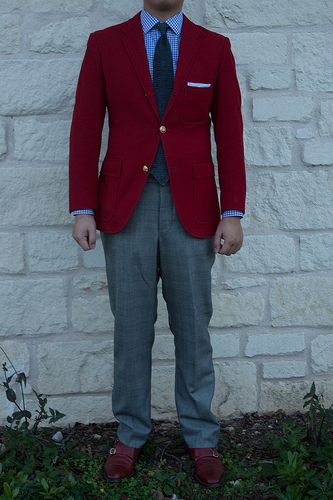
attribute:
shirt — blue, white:
[138, 8, 183, 81]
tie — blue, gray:
[152, 19, 172, 191]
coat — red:
[68, 11, 247, 242]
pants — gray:
[101, 174, 220, 450]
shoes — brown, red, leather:
[101, 441, 227, 488]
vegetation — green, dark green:
[0, 346, 328, 498]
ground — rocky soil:
[3, 408, 331, 499]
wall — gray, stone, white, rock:
[0, 3, 331, 428]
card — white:
[186, 81, 214, 88]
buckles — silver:
[105, 447, 222, 459]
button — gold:
[157, 125, 168, 133]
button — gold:
[138, 163, 150, 173]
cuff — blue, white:
[68, 209, 97, 219]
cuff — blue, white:
[219, 210, 244, 220]